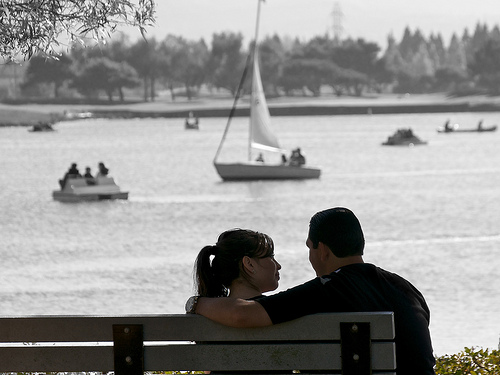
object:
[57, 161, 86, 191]
people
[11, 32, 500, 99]
outdoors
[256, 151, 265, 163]
person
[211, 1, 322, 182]
sailboat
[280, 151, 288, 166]
person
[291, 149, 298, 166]
person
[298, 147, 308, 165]
person